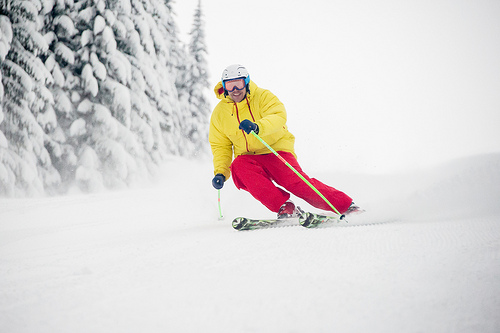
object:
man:
[204, 63, 365, 222]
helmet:
[220, 63, 253, 99]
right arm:
[207, 114, 232, 173]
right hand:
[210, 172, 228, 191]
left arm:
[259, 92, 289, 137]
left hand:
[236, 120, 256, 135]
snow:
[0, 151, 499, 332]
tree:
[0, 0, 62, 201]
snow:
[0, 0, 58, 198]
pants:
[226, 150, 353, 213]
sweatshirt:
[205, 80, 297, 182]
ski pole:
[251, 130, 350, 226]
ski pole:
[215, 177, 220, 222]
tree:
[186, 0, 217, 167]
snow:
[183, 1, 222, 171]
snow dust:
[83, 150, 207, 216]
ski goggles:
[219, 79, 247, 92]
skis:
[297, 210, 385, 229]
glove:
[235, 117, 263, 136]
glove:
[209, 175, 227, 189]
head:
[219, 64, 249, 105]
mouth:
[230, 90, 244, 100]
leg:
[227, 156, 282, 212]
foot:
[337, 199, 365, 223]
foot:
[273, 201, 312, 219]